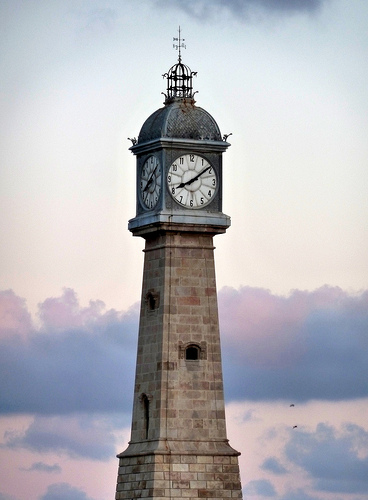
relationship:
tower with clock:
[127, 66, 251, 481] [160, 148, 281, 255]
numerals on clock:
[170, 155, 206, 183] [160, 148, 281, 255]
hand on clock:
[175, 158, 240, 197] [160, 148, 281, 255]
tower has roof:
[127, 66, 251, 481] [127, 86, 207, 122]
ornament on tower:
[119, 53, 222, 97] [127, 66, 251, 481]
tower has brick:
[127, 66, 251, 481] [176, 262, 201, 281]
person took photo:
[239, 476, 340, 499] [47, 19, 331, 491]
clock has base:
[160, 148, 281, 255] [133, 212, 243, 299]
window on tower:
[175, 338, 236, 383] [127, 66, 251, 481]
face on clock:
[162, 154, 201, 186] [160, 148, 281, 255]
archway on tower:
[127, 408, 174, 444] [127, 66, 251, 481]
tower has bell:
[127, 66, 251, 481] [157, 57, 252, 169]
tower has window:
[127, 66, 251, 481] [175, 338, 236, 383]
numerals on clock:
[188, 155, 196, 166] [160, 148, 281, 255]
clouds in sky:
[33, 59, 135, 384] [24, 224, 122, 355]